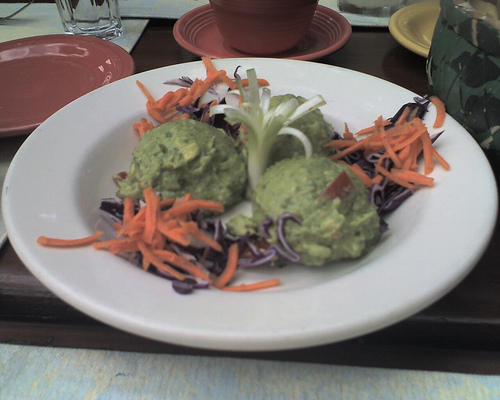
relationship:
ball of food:
[115, 117, 249, 212] [262, 152, 383, 267]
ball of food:
[251, 153, 382, 266] [262, 152, 383, 267]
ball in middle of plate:
[115, 117, 249, 212] [19, 33, 489, 365]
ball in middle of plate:
[251, 153, 382, 266] [19, 33, 489, 365]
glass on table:
[50, 1, 131, 39] [10, 275, 498, 386]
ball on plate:
[251, 153, 382, 266] [19, 33, 489, 365]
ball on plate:
[242, 150, 387, 270] [19, 33, 489, 365]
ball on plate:
[115, 110, 249, 212] [19, 33, 489, 365]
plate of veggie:
[19, 33, 489, 365] [38, 227, 107, 251]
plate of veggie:
[19, 33, 489, 365] [139, 181, 162, 249]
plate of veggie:
[19, 33, 489, 365] [425, 87, 448, 131]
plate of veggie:
[19, 33, 489, 365] [200, 50, 236, 86]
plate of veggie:
[19, 33, 489, 365] [207, 63, 329, 204]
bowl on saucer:
[206, 1, 321, 56] [171, 1, 350, 61]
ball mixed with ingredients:
[251, 153, 382, 266] [113, 75, 421, 285]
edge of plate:
[177, 329, 336, 351] [0, 56, 499, 353]